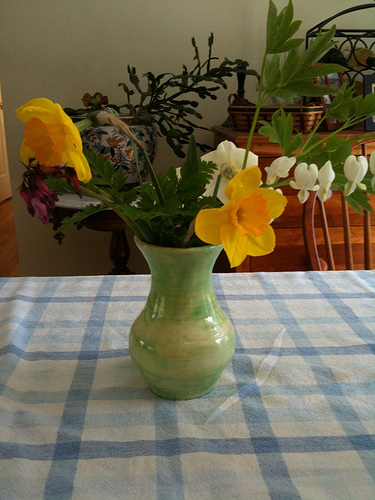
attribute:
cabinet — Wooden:
[281, 214, 306, 269]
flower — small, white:
[196, 134, 259, 215]